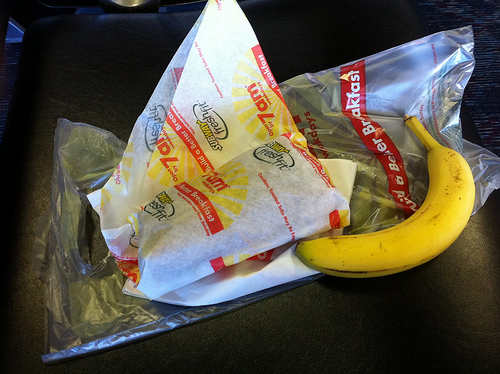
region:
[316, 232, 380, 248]
brown part of banana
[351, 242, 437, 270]
yellow part of banana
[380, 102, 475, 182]
top of the banana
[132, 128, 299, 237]
wrapper over the sandwich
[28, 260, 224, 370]
bag thats holding something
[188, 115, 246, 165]
green and yellow logo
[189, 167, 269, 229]
yellow print on wrapper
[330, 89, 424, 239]
red logo on bag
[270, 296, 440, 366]
black table holding sandwich bag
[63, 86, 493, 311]
sandwich bag and banana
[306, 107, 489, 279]
banana laying on bag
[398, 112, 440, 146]
end stem of banana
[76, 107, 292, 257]
subway wrapper on bag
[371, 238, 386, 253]
brown spot on banana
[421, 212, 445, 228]
brown spot on banana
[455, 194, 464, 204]
brown spot on banana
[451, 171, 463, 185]
brown spot on banana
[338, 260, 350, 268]
brown spot on banana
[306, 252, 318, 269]
brown spot on banana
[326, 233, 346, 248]
brown spot on banana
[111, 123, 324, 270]
A sandwich wrapped in paper.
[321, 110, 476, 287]
A banana.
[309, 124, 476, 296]
The banana is yellow.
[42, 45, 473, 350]
The bag is clear.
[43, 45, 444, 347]
The bag is made of plastic.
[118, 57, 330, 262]
The paper is white.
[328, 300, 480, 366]
The background is black.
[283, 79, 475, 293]
The banana is ripe.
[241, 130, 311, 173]
A logo on the paper.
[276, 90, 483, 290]
ripe yellow banana with spots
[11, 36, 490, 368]
group of different foods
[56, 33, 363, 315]
breakfast sandwich in wrapper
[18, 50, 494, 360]
clear plastic food bag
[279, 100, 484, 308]
ripe yellow banana for eating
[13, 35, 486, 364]
breakfast sandwich from subway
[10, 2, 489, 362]
small balanced breakfast meal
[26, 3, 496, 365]
food sitting on plastic bag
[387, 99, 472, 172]
stem of a ripe banana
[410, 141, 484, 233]
banana with brown spots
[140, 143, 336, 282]
sandwich wrapped in paper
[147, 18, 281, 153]
paper wrapping partially open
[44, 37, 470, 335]
long plastic sandwich bag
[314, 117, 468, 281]
banana on plastic bag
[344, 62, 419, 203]
white words on red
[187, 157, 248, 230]
yellow sun design on paper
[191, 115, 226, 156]
logo of sandwich restaurant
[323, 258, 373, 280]
discoloration on edge of banana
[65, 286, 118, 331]
light reflection on plastic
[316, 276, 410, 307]
shadow on black surface